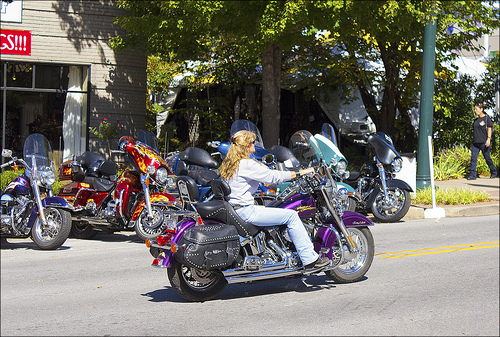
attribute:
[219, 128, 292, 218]
woman — riding, wearing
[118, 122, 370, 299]
motorcycle — purple, parked, red, green, blue, black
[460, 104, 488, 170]
woman — walking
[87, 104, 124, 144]
rose — red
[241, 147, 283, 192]
rider — female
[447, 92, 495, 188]
person — walking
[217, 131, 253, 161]
hair — red, blonde, clip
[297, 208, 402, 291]
bike — purple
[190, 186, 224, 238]
saddle — black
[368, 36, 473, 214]
pole — green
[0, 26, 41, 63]
sign — red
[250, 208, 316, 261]
jean — denim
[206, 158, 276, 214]
shirt — grey, white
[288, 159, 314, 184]
watch — black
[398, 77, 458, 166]
post — green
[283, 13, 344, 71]
leave — green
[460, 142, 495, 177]
short — black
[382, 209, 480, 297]
line — yellow